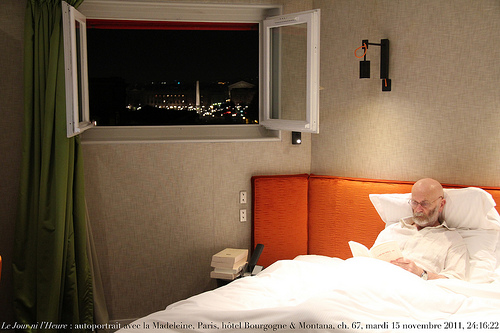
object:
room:
[4, 6, 499, 332]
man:
[368, 178, 469, 281]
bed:
[115, 175, 499, 329]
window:
[63, 0, 322, 140]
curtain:
[0, 0, 115, 333]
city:
[123, 72, 256, 121]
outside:
[87, 29, 257, 123]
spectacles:
[407, 196, 443, 209]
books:
[209, 247, 249, 280]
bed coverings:
[117, 252, 499, 333]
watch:
[421, 269, 428, 280]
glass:
[271, 26, 306, 121]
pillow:
[368, 186, 499, 228]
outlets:
[239, 189, 247, 222]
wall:
[1, 2, 497, 321]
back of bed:
[253, 173, 499, 267]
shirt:
[369, 216, 468, 281]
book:
[348, 240, 403, 263]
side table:
[215, 266, 262, 290]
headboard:
[251, 172, 499, 276]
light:
[354, 39, 392, 92]